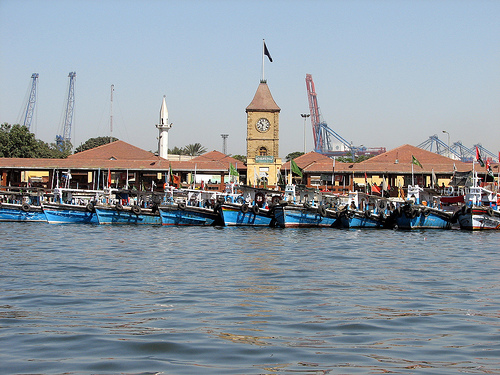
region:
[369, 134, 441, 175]
the roof is red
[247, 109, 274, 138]
the clock is on the tower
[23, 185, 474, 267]
the boats are docked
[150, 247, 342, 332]
the water is calm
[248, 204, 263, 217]
lifejackets are tires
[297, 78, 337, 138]
the crane is red in color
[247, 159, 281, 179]
the wall is brown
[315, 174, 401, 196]
people are on the dock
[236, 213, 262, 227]
shadow is on the boat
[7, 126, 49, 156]
tree is in the background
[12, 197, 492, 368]
body of water with boats in it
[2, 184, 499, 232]
boats lined up in water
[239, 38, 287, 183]
tower with clock and flag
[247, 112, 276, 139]
area on tower with clock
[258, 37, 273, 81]
flag on top of tower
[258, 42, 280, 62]
banner part of flag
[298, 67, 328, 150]
red crane in back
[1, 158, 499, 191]
covered structure behind boats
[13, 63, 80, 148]
two cranes behind the boats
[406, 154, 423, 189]
flag on ground near boats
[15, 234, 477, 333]
ripples on the water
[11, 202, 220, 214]
tires on the sides of boats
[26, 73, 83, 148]
large blue construction cranes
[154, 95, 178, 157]
white pointed tower behind building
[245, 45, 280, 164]
large white clock on tower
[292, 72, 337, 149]
large red construction crane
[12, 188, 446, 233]
many blue and black boats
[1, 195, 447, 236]
blue boats with black stripes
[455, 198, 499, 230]
red and white boat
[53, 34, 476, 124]
blue sky and no clouds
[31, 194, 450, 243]
many boats on the water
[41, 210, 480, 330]
a body of blue water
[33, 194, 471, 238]
blue and black boats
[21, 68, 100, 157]
two large cranes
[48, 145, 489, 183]
large building behind the water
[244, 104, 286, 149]
clock on a tower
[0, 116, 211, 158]
trees behind building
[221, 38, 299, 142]
flag on top of tower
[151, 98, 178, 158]
white tower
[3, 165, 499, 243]
boats moored at dock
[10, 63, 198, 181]
cranes are in the background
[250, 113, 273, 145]
clock atop a tower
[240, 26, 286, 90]
tower has a flag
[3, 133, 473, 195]
brown roofs on the buildings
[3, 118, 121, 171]
green trees behind the buildings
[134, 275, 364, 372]
ripples in the ocean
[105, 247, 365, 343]
calm ocean water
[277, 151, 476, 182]
flags on the boats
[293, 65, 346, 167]
red crane behind building